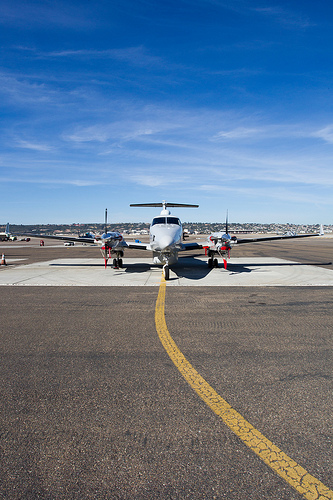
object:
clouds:
[307, 155, 330, 189]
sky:
[0, 2, 332, 224]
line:
[156, 274, 330, 500]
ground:
[0, 236, 332, 499]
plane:
[13, 201, 322, 279]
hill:
[2, 222, 150, 241]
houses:
[234, 224, 331, 235]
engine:
[215, 236, 232, 254]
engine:
[100, 231, 117, 249]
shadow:
[170, 252, 211, 279]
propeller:
[101, 207, 109, 270]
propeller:
[222, 209, 230, 266]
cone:
[2, 253, 7, 266]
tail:
[129, 201, 199, 210]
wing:
[181, 233, 322, 255]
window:
[167, 216, 179, 225]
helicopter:
[77, 230, 99, 241]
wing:
[11, 231, 147, 249]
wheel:
[163, 264, 168, 278]